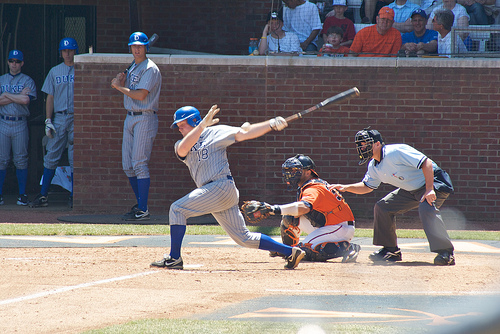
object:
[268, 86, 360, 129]
bat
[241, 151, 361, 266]
catcher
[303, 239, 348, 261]
shin guards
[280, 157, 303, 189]
catcher's mask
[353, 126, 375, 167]
catcher's mask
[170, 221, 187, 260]
sock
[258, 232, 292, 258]
sock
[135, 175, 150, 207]
sock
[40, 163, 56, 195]
sock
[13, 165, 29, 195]
sock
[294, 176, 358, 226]
shirt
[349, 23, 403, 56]
shirt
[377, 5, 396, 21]
hat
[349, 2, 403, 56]
man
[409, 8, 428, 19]
hat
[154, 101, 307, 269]
baseball player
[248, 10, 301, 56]
people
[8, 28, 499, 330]
game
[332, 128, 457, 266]
umpire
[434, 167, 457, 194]
bag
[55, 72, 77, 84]
school name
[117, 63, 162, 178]
uniform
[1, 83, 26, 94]
school name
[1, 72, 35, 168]
uniform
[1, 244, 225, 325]
dirt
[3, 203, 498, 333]
baseball field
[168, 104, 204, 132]
helmet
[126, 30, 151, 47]
helmet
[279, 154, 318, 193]
helmet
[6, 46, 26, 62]
helmet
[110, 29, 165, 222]
baseball player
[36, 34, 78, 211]
baseball player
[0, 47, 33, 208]
baseball player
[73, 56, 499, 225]
wall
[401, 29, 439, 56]
shirt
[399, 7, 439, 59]
man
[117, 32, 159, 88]
bat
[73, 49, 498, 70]
top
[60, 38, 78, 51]
hat